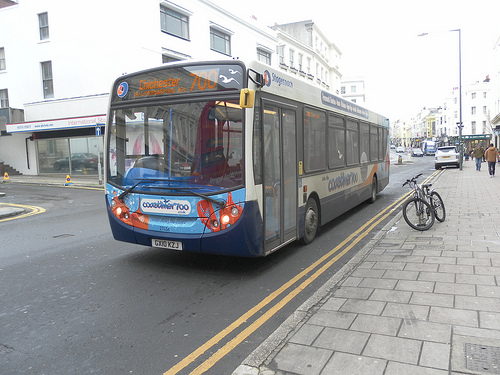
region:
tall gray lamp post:
[455, 28, 468, 170]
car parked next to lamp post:
[433, 145, 460, 170]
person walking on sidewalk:
[482, 142, 499, 174]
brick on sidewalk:
[310, 327, 370, 358]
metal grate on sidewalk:
[462, 342, 499, 373]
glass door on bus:
[259, 101, 301, 248]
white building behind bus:
[0, 0, 278, 180]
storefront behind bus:
[0, 90, 111, 177]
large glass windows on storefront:
[33, 136, 72, 178]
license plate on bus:
[149, 237, 183, 253]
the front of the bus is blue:
[85, 44, 325, 279]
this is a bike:
[390, 158, 472, 283]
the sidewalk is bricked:
[382, 287, 487, 354]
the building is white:
[42, 31, 214, 205]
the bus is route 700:
[105, 67, 252, 108]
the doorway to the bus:
[231, 68, 333, 260]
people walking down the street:
[436, 129, 498, 197]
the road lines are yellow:
[224, 308, 301, 347]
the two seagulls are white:
[209, 63, 250, 95]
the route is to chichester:
[124, 66, 201, 104]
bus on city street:
[93, 52, 395, 294]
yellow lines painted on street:
[210, 283, 290, 337]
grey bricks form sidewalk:
[350, 265, 455, 335]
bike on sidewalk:
[397, 163, 449, 240]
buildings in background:
[322, 6, 470, 129]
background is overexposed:
[397, 103, 487, 128]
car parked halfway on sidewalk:
[425, 141, 461, 176]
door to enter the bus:
[245, 84, 310, 246]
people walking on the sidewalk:
[466, 132, 496, 176]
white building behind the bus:
[7, 5, 350, 203]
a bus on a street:
[82, 44, 402, 268]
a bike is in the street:
[381, 167, 456, 247]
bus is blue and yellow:
[80, 42, 404, 267]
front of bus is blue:
[91, 48, 271, 272]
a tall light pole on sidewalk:
[407, 11, 472, 175]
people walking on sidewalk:
[458, 135, 498, 176]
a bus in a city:
[1, 10, 498, 307]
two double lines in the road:
[155, 255, 330, 373]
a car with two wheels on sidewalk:
[427, 137, 468, 175]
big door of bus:
[240, 91, 312, 258]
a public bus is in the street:
[103, 56, 390, 265]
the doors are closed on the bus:
[256, 95, 304, 255]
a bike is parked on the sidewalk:
[396, 170, 450, 236]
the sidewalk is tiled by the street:
[290, 160, 495, 374]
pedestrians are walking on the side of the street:
[394, 117, 499, 169]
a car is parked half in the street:
[431, 142, 463, 173]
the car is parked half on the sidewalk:
[429, 142, 464, 177]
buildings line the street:
[290, 67, 499, 169]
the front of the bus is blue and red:
[101, 72, 265, 265]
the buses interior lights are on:
[181, 94, 309, 144]